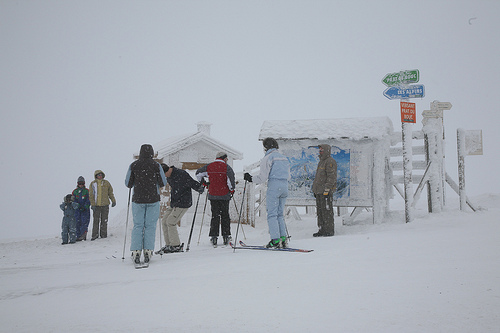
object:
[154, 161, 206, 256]
person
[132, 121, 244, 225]
building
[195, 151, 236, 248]
person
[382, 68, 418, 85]
sign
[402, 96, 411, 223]
pole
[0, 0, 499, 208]
bag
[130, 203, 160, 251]
blue pants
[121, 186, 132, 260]
skis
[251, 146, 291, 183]
jacket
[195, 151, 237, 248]
man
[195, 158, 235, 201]
red jacket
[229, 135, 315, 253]
woman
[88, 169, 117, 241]
people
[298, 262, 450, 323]
snow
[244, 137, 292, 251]
man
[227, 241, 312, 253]
ski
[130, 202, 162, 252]
pants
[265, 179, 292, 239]
blue pants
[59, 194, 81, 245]
person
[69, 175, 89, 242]
person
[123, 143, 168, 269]
person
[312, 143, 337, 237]
person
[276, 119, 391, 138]
snow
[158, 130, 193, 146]
snow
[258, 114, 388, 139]
roof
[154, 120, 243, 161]
roof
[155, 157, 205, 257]
person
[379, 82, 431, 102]
sign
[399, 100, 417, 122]
red sign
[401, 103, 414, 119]
lettering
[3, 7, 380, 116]
sky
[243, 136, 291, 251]
person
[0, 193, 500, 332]
ground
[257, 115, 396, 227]
building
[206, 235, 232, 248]
skis